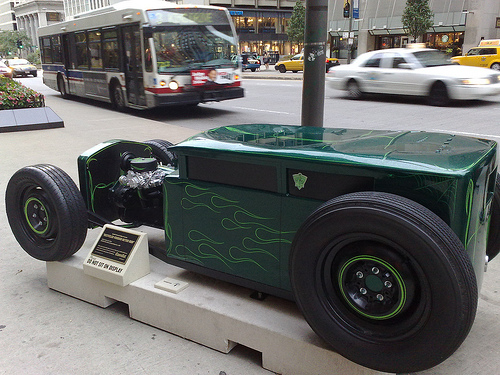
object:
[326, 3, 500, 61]
store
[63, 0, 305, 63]
building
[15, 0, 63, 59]
building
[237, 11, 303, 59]
windows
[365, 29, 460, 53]
windows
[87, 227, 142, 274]
plaque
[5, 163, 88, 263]
small wheel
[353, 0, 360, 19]
sign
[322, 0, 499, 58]
building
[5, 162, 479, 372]
motorbox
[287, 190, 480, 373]
tires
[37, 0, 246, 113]
bus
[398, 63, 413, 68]
mirror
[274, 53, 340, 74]
car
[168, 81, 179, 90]
light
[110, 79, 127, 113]
tire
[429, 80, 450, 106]
tire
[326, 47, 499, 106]
car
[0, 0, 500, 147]
city street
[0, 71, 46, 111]
flower beds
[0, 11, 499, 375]
traffic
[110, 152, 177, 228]
engine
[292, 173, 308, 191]
sticker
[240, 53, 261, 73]
car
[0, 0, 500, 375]
city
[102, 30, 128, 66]
window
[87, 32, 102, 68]
window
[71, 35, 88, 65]
window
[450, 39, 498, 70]
car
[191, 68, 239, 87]
sign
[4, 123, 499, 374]
car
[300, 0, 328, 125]
pole